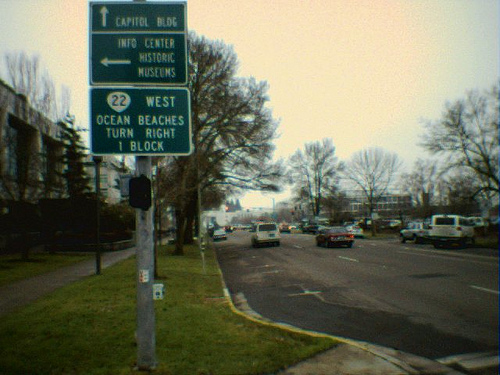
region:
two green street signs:
[87, 6, 199, 150]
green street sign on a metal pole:
[93, 8, 188, 323]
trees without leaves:
[428, 103, 497, 182]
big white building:
[313, 186, 407, 222]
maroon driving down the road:
[316, 222, 358, 249]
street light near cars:
[237, 203, 297, 220]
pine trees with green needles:
[57, 110, 87, 210]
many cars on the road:
[218, 209, 462, 261]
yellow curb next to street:
[221, 283, 381, 360]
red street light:
[218, 200, 242, 218]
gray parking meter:
[196, 232, 208, 272]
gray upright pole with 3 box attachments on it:
[129, 157, 166, 369]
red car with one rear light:
[316, 226, 356, 248]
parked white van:
[428, 213, 476, 246]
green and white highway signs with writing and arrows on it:
[86, 0, 196, 157]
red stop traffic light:
[223, 206, 228, 212]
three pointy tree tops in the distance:
[225, 198, 242, 211]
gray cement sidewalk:
[3, 232, 173, 322]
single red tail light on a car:
[348, 233, 354, 240]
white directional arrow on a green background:
[99, 56, 129, 66]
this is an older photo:
[39, 16, 454, 353]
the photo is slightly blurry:
[27, 49, 379, 309]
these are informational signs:
[64, 16, 197, 186]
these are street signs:
[55, 19, 224, 179]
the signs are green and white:
[76, 7, 233, 164]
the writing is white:
[69, 19, 209, 166]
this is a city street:
[223, 209, 492, 369]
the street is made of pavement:
[281, 249, 431, 316]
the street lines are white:
[256, 245, 460, 323]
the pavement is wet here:
[259, 276, 416, 359]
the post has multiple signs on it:
[82, 7, 197, 170]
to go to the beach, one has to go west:
[78, 96, 207, 159]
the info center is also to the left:
[93, 33, 192, 86]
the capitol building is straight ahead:
[90, 4, 195, 34]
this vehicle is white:
[252, 214, 284, 250]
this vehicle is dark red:
[317, 215, 359, 250]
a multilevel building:
[304, 188, 426, 227]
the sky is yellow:
[299, 60, 399, 102]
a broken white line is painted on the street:
[287, 237, 494, 327]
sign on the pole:
[89, 87, 191, 158]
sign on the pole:
[90, 34, 192, 86]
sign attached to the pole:
[91, 87, 189, 155]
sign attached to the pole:
[91, 2, 187, 84]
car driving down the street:
[251, 219, 283, 249]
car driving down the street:
[312, 224, 360, 244]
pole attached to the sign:
[136, 159, 157, 373]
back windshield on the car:
[260, 223, 279, 233]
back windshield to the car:
[331, 227, 348, 234]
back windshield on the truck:
[436, 217, 456, 225]